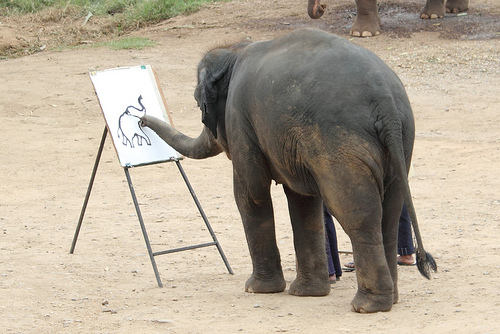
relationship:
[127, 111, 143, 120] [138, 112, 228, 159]
paintbrush held by trunk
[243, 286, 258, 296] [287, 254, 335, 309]
toe nails on elephant foot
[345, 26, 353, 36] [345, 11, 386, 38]
toe nail of elephant foot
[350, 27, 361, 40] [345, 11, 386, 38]
toe nail of elephant foot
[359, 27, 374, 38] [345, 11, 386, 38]
toe nail of elephant foot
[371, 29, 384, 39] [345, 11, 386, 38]
toe nail of elephant foot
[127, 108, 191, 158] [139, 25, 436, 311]
trunk of elephant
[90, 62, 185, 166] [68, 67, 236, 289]
paper pad on easel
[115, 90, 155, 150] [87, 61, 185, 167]
drawing on paper pad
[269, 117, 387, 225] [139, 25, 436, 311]
dirt on elephant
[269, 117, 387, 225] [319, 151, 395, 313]
dirt on leg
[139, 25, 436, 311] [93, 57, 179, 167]
elephant painting a picture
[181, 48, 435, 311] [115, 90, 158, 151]
elephant drawing drawing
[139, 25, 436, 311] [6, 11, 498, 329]
elephant on dirt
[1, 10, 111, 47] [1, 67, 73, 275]
dried hay on ground